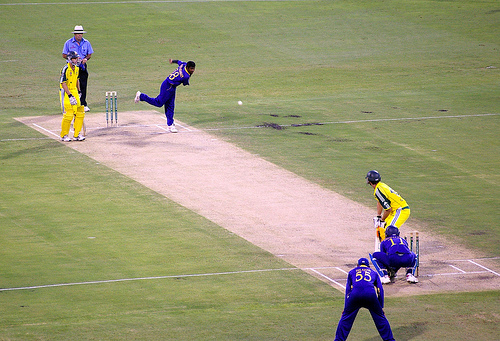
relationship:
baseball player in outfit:
[365, 168, 410, 237] [373, 182, 408, 237]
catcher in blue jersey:
[369, 225, 422, 286] [381, 236, 411, 258]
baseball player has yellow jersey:
[58, 50, 90, 143] [372, 183, 409, 208]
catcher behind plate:
[367, 225, 416, 282] [354, 252, 427, 280]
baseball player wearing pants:
[58, 50, 90, 143] [55, 90, 90, 140]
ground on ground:
[12, 60, 499, 314] [12, 60, 499, 314]